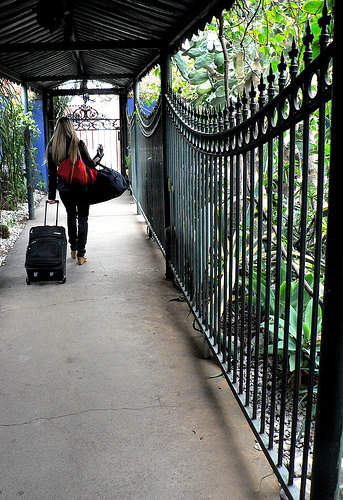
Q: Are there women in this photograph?
A: Yes, there is a woman.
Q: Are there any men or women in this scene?
A: Yes, there is a woman.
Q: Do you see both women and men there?
A: No, there is a woman but no men.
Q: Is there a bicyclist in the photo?
A: No, there are no cyclists.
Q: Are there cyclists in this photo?
A: No, there are no cyclists.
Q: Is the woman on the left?
A: Yes, the woman is on the left of the image.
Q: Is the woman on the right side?
A: No, the woman is on the left of the image.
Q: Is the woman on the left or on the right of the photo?
A: The woman is on the left of the image.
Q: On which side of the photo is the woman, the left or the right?
A: The woman is on the left of the image.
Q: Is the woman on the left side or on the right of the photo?
A: The woman is on the left of the image.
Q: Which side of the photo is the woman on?
A: The woman is on the left of the image.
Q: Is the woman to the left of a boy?
A: No, the woman is to the left of the bag.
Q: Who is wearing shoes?
A: The woman is wearing shoes.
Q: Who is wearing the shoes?
A: The woman is wearing shoes.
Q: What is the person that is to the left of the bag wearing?
A: The woman is wearing shoes.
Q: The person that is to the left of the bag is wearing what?
A: The woman is wearing shoes.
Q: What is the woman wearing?
A: The woman is wearing shoes.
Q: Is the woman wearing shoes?
A: Yes, the woman is wearing shoes.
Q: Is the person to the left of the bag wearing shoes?
A: Yes, the woman is wearing shoes.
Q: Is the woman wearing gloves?
A: No, the woman is wearing shoes.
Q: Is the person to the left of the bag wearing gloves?
A: No, the woman is wearing shoes.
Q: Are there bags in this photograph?
A: Yes, there is a bag.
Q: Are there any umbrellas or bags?
A: Yes, there is a bag.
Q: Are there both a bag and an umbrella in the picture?
A: No, there is a bag but no umbrellas.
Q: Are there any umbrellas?
A: No, there are no umbrellas.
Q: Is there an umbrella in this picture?
A: No, there are no umbrellas.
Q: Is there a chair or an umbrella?
A: No, there are no umbrellas or chairs.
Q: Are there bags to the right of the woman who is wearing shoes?
A: Yes, there is a bag to the right of the woman.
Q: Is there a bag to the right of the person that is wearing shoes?
A: Yes, there is a bag to the right of the woman.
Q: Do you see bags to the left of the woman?
A: No, the bag is to the right of the woman.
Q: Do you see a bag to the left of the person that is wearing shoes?
A: No, the bag is to the right of the woman.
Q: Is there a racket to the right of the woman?
A: No, there is a bag to the right of the woman.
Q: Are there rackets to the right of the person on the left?
A: No, there is a bag to the right of the woman.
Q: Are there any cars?
A: No, there are no cars.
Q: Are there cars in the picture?
A: No, there are no cars.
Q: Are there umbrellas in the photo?
A: No, there are no umbrellas.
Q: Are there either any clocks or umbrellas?
A: No, there are no umbrellas or clocks.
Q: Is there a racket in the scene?
A: No, there are no rackets.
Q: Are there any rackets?
A: No, there are no rackets.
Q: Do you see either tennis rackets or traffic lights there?
A: No, there are no tennis rackets or traffic lights.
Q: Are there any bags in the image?
A: Yes, there is a bag.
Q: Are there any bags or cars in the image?
A: Yes, there is a bag.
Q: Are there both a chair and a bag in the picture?
A: No, there is a bag but no chairs.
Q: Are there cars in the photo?
A: No, there are no cars.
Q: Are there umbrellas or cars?
A: No, there are no cars or umbrellas.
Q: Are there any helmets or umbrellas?
A: No, there are no umbrellas or helmets.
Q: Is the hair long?
A: Yes, the hair is long.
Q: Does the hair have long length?
A: Yes, the hair is long.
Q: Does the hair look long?
A: Yes, the hair is long.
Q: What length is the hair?
A: The hair is long.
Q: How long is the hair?
A: The hair is long.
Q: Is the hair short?
A: No, the hair is long.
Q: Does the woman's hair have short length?
A: No, the hair is long.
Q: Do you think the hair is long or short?
A: The hair is long.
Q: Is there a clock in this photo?
A: No, there are no clocks.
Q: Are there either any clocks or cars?
A: No, there are no clocks or cars.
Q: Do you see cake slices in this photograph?
A: No, there are no cake slices.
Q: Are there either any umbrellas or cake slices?
A: No, there are no cake slices or umbrellas.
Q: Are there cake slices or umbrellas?
A: No, there are no cake slices or umbrellas.